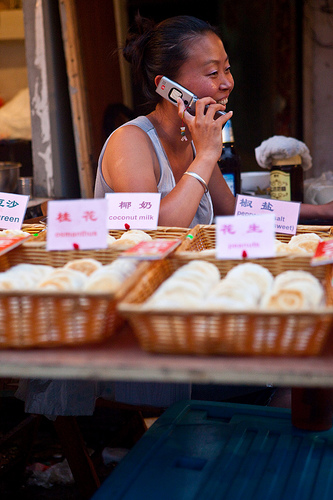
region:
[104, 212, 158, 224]
'Coconut milk' written in purple.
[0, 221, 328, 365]
Cookies in basket on display.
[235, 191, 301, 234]
Pink sign with blue letters.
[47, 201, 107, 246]
Pink sign with red letters.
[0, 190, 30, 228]
Pink sign with green letters.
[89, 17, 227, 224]
Woman talking on cell phone.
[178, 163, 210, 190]
Silver bracelet worn by a woman.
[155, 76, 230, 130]
Sliver colored cell phone.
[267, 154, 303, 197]
Brown jar with yellow label and top.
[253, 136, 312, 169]
White rag on jar top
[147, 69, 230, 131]
open clam shell cell phone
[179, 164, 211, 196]
metal bracelet on wrist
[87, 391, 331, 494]
lid of plastic container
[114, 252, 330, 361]
weaved basket of pastries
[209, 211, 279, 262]
pastry name placard attached to weaved basket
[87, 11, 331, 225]
woman sitting at table talking on cell phone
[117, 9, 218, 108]
bun hair style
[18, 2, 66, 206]
edge of grey stone wall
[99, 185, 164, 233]
coconut milk sign sign attached to weaved basket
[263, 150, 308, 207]
clear jar with brown liquid in it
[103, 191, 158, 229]
pink and purple Coconut milk label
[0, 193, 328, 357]
A table of deserts and sweets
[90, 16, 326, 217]
Lady talking on her cell phone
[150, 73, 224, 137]
Silver flip phone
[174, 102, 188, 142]
cute cell phone charm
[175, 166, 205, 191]
Silver bracelet on woman's arm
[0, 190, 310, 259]
5 pink food labels.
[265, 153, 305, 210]
Yellow and brown jar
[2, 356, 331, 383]
White table for the food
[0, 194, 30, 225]
Pink and green food label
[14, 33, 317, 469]
Woman on cellphone in front of food display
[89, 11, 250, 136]
Woman speaking on cellphone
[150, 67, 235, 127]
Flip phone held to ear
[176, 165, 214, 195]
Silver bangle on wrist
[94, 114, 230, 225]
Sleeveless grey & white blouse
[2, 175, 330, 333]
Pastries in straw baskets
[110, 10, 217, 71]
Brunette hair in bun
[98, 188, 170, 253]
Coconut flavored food in basket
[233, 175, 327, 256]
Pepper and salt food in basket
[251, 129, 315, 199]
Rag sitting atop jar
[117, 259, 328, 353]
a brown wicker basket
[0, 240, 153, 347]
a brown wicker basket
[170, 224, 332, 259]
a brown wicker basket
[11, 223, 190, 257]
a brown wicker basket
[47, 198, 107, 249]
a small price sign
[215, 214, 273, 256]
a small price sign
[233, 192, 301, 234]
a small price sign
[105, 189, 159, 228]
a small price sign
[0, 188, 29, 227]
a small price sign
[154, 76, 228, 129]
a cellular flip phone